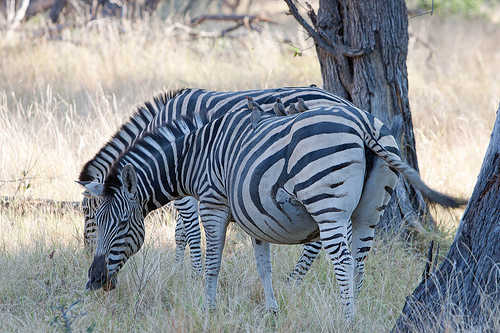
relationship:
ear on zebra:
[109, 158, 143, 208] [69, 95, 453, 332]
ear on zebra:
[70, 178, 107, 206] [69, 95, 453, 332]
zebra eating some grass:
[84, 100, 470, 322] [5, 200, 498, 331]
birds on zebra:
[243, 96, 305, 118] [84, 106, 404, 307]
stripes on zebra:
[194, 121, 333, 233] [84, 100, 470, 322]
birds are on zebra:
[235, 81, 336, 125] [84, 100, 470, 322]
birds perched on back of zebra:
[237, 91, 312, 127] [86, 121, 376, 319]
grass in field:
[129, 255, 197, 330] [2, 11, 497, 331]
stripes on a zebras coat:
[232, 132, 272, 197] [142, 105, 344, 231]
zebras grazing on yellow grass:
[64, 86, 498, 317] [35, 261, 183, 328]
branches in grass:
[138, 17, 331, 59] [9, 252, 338, 312]